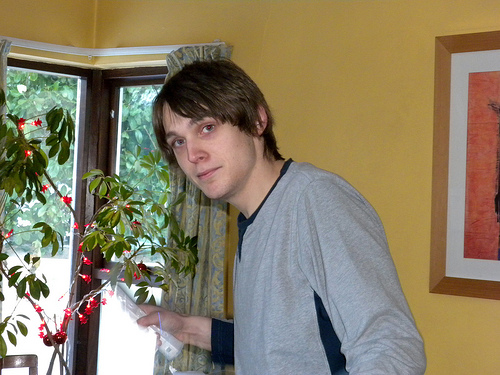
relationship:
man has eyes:
[135, 57, 427, 374] [175, 130, 215, 143]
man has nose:
[135, 57, 427, 374] [192, 138, 195, 162]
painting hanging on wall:
[462, 69, 499, 265] [295, 83, 451, 141]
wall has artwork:
[358, 145, 418, 166] [431, 145, 491, 196]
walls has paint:
[302, 115, 376, 125] [313, 100, 329, 120]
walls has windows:
[331, 123, 385, 134] [35, 150, 143, 186]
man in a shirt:
[135, 57, 427, 374] [237, 174, 407, 370]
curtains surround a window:
[165, 43, 225, 370] [0, 36, 240, 371]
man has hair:
[115, 50, 418, 360] [150, 56, 284, 181]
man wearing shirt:
[115, 50, 418, 360] [210, 161, 445, 361]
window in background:
[0, 58, 222, 374] [1, 11, 235, 355]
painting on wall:
[462, 69, 499, 265] [95, 2, 498, 374]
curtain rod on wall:
[1, 33, 224, 69] [8, 13, 482, 370]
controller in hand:
[109, 285, 186, 365] [128, 299, 188, 350]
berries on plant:
[62, 295, 101, 327] [6, 102, 201, 373]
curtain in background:
[155, 38, 232, 374] [1, 11, 235, 355]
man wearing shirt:
[135, 57, 427, 374] [207, 154, 430, 374]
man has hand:
[135, 57, 427, 374] [135, 298, 188, 347]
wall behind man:
[0, 0, 98, 54] [135, 57, 427, 374]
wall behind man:
[95, 2, 498, 374] [135, 57, 427, 374]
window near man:
[98, 85, 179, 374] [135, 57, 427, 374]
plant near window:
[0, 107, 199, 374] [0, 65, 80, 372]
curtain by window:
[155, 38, 232, 374] [98, 85, 179, 374]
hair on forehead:
[150, 56, 284, 181] [155, 100, 206, 129]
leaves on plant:
[0, 108, 197, 348] [0, 107, 199, 374]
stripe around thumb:
[154, 312, 163, 329] [135, 306, 165, 326]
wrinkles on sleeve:
[341, 307, 431, 374] [299, 179, 425, 374]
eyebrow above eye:
[161, 127, 179, 144] [168, 135, 186, 149]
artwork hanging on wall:
[425, 27, 499, 307] [244, 9, 498, 262]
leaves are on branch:
[40, 102, 77, 163] [16, 110, 47, 141]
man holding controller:
[135, 57, 427, 374] [109, 285, 186, 365]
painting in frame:
[458, 62, 498, 269] [425, 30, 462, 298]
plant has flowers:
[6, 102, 201, 373] [76, 252, 91, 283]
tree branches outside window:
[4, 92, 198, 298] [7, 61, 187, 367]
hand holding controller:
[136, 295, 197, 347] [109, 285, 186, 365]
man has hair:
[135, 57, 427, 374] [170, 58, 252, 111]